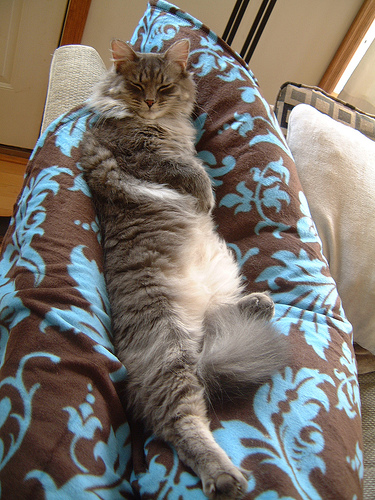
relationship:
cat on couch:
[76, 29, 305, 498] [3, 43, 373, 498]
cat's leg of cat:
[169, 409, 229, 474] [76, 29, 305, 498]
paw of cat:
[199, 466, 250, 498] [65, 19, 340, 471]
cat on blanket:
[76, 29, 293, 499] [3, 5, 368, 496]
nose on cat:
[145, 94, 155, 121] [50, 21, 348, 483]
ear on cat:
[162, 37, 191, 68] [76, 29, 305, 498]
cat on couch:
[76, 29, 293, 499] [23, 37, 116, 152]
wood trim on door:
[54, 0, 90, 48] [0, 1, 68, 151]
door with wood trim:
[0, 1, 68, 151] [0, 145, 32, 164]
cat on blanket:
[76, 29, 293, 499] [1, 310, 128, 498]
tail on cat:
[200, 303, 290, 391] [76, 29, 305, 498]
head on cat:
[92, 30, 202, 121] [76, 29, 305, 498]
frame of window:
[317, 3, 371, 100] [334, 23, 373, 113]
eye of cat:
[130, 77, 144, 93] [82, 35, 197, 129]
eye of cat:
[155, 80, 173, 95] [76, 29, 305, 498]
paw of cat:
[199, 466, 250, 498] [85, 38, 276, 498]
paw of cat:
[235, 290, 275, 325] [83, 46, 264, 329]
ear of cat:
[107, 36, 136, 70] [44, 46, 296, 362]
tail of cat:
[200, 303, 290, 395] [85, 38, 276, 498]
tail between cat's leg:
[200, 303, 290, 395] [230, 291, 274, 321]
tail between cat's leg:
[200, 303, 290, 395] [132, 358, 247, 497]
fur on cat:
[112, 212, 190, 315] [76, 29, 305, 498]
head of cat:
[97, 30, 202, 121] [85, 54, 288, 414]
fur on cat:
[173, 220, 238, 327] [93, 33, 293, 499]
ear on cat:
[162, 37, 191, 68] [85, 38, 276, 498]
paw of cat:
[192, 466, 250, 497] [76, 29, 305, 498]